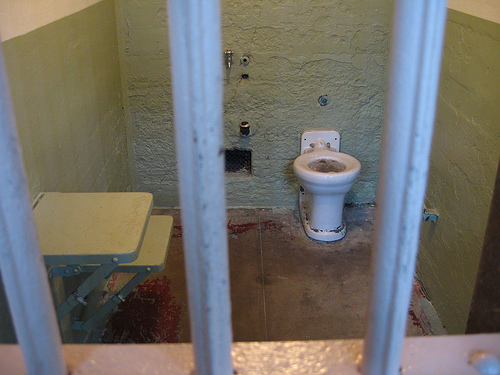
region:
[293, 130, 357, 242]
a small porcelain toilet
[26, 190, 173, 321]
two small metal shelves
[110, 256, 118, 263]
small metal bolt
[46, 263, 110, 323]
a metal hinge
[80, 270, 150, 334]
a metal hinge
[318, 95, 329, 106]
button for flushing a toilet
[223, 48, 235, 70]
water nozzle in a wall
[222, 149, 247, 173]
metal grate in the wall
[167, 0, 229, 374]
a metal pole in a window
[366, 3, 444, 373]
a metal pole in a window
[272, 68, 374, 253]
a toilet inside of a jail cell.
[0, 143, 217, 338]
a table inside of a jail cell.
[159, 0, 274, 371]
a large metal pole.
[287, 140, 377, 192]
a lid on a toilet.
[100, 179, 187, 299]
a seat at a bench.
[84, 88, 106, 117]
a tile on a wall.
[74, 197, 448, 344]
a tile covered floor.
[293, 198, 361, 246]
a bolted down toilet.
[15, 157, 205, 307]
a small bench.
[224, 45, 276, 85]
faucet on a wall.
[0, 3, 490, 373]
a small prison cell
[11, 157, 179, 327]
a table mounted on the wall in a prison cell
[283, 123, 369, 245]
a small disgusting toilet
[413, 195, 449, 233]
toilet paper rolls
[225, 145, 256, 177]
a vent in the side of a wall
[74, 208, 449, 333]
the floor on a prison cell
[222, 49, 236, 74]
a water faucet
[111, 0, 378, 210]
a green painted wall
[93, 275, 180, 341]
red paint on a concrete floor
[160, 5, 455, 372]
the bars on a prison cell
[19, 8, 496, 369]
this appears to be a jail cell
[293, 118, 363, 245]
the toilet is white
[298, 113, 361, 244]
the toilet appears to need to be cleaned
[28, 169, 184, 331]
a table & seat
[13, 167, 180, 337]
both of these are attached to the wall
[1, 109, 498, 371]
the cell bars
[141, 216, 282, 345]
it appears there is blood on the floor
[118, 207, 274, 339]
maybe it's just red paint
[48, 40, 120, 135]
the wall is painted green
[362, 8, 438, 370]
the bar is made of steel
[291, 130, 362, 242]
Toilet in a jail cell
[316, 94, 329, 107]
Mechanism to flush the toilet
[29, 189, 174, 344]
Retractable tabletops bolted to the wall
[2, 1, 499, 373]
Bars on a jail cell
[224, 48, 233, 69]
Water faucet in a jail cell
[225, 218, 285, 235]
Red stain on floor of jail cell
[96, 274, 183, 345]
Large red stain on the floor of a jail cell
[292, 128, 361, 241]
One-piece toilet in a jail cell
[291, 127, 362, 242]
Dirty toilet in a jail cell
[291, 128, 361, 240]
Toilet without a cover or seat